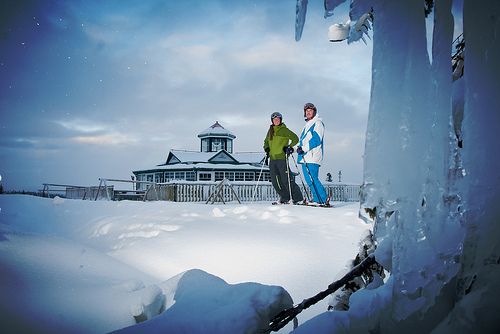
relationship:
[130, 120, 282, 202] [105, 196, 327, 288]
house in snow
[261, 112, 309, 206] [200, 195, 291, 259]
person on snow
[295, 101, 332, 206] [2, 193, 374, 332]
man to left on snow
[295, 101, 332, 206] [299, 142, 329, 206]
man holding ski pole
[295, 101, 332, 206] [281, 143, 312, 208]
man holding ski pole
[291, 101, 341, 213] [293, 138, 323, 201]
man holding ski pole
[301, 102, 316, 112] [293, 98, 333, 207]
snow goggles on man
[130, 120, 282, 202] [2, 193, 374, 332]
house covered with snow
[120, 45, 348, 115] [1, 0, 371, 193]
clouds in cloudy sky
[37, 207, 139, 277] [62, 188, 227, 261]
snow covers ground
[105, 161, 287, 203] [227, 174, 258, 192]
wooden fence covered with snow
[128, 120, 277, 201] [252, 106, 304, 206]
house behind person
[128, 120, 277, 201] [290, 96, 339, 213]
house behind person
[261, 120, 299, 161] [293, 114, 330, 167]
coat wearing coat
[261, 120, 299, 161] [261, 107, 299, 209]
coat wearing person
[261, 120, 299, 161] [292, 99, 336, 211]
coat wearing person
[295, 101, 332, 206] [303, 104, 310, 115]
man has hair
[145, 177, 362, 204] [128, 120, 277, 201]
wooden fence around house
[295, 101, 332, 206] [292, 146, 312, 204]
man holding ski pole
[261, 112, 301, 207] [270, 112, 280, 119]
person with snow goggles